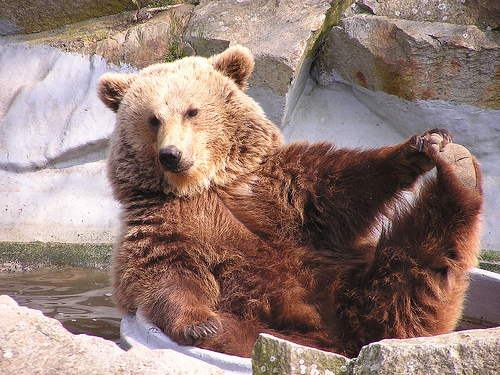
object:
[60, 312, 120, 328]
ripples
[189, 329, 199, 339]
claw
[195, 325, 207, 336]
claw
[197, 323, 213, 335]
claw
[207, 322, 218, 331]
claw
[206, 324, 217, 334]
claw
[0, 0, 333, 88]
rocks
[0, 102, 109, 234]
rocks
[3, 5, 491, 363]
enclave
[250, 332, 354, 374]
rock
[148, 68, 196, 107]
hair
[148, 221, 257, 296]
fur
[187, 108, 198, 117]
black eyes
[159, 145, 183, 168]
black nose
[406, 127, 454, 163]
left paw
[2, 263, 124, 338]
water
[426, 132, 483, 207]
foot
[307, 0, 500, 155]
rock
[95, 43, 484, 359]
animal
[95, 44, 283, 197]
head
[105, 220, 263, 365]
back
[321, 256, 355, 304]
patch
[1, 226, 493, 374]
pool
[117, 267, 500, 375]
tub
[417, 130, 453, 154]
claws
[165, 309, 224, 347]
hand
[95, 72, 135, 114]
ear